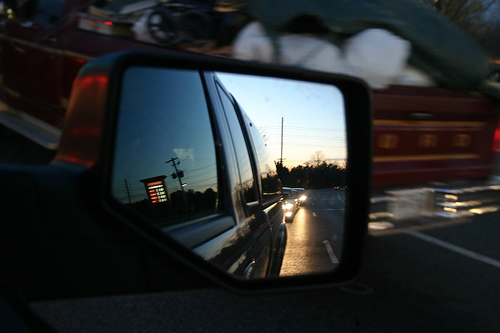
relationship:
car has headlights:
[282, 188, 295, 222] [286, 202, 294, 218]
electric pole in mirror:
[168, 156, 194, 213] [113, 68, 344, 282]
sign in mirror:
[146, 182, 166, 203] [113, 68, 344, 282]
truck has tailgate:
[2, 4, 498, 233] [370, 83, 496, 185]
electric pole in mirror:
[122, 179, 132, 205] [113, 68, 344, 282]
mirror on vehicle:
[113, 68, 344, 282] [1, 64, 371, 331]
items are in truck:
[79, 2, 493, 91] [2, 4, 498, 233]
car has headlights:
[295, 188, 309, 204] [299, 194, 307, 203]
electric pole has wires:
[168, 156, 194, 213] [112, 157, 249, 200]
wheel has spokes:
[146, 9, 180, 43] [151, 17, 173, 37]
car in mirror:
[282, 188, 295, 222] [113, 68, 344, 282]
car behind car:
[282, 188, 295, 222] [113, 64, 287, 280]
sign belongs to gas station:
[146, 182, 166, 203] [139, 175, 173, 219]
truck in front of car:
[2, 4, 498, 233] [113, 64, 287, 280]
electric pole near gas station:
[168, 156, 194, 213] [139, 175, 173, 219]